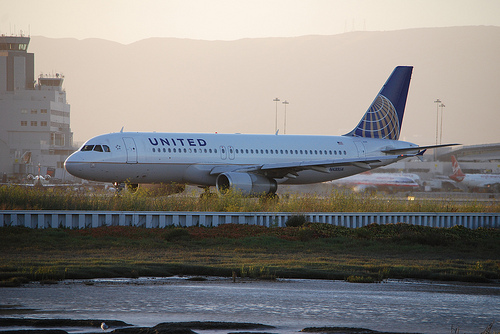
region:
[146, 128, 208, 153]
This airplane says that it is "United"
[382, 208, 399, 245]
There is a white fence that is visible here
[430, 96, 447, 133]
There are large lamps that are visible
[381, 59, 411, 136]
There is a blue tail that is on this airplane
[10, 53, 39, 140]
There is a gray building that is visible here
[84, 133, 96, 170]
There is a small window that is visible here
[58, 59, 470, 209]
airplane on tarmac near airport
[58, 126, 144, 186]
nose of airplane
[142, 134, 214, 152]
name of company that owns the airplane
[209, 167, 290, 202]
jet engine of the left wing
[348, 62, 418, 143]
tail of the United airplae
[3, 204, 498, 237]
fence near the tarmac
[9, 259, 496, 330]
water in pond near the tarmac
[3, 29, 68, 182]
airport and control tower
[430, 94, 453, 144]
light poles at airport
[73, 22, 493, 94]
mountains near the airport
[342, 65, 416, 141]
Image of a globe on blue tail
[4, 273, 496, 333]
Water beside airport runway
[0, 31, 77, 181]
Air traffic control tower on building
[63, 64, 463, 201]
Large commercial airliner parked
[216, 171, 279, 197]
Engine on an airplane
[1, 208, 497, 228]
White retaining wall beside runway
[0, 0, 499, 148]
Hazy daytime sky behind plane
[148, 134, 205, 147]
United logo printed on plane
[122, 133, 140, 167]
Entry door to plane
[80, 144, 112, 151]
Cockpit windows on plane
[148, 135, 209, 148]
A logo on the side of a plane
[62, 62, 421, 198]
A large plane on the ground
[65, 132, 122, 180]
The cockpit of a plane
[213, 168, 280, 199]
A plane's engine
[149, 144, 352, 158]
A row of windows along a plane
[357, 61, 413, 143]
The colored tail wing of the plane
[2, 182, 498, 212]
A line of grass and weeds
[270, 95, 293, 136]
Light posts on the airport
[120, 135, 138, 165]
The door of the plane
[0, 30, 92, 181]
Part of the airport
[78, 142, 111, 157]
Front windows on an airplane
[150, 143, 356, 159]
Side windows on the airplane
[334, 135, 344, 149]
United states flag on the airplane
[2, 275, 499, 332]
Water and a few rocks on the side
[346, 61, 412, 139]
Blue tail on the airplane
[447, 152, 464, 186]
Red tail on the airplane in the back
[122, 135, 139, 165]
Side door on the airplane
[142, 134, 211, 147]
United written on the side of the plane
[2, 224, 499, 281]
A long stretch of grass next to the water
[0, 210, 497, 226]
Long white thin gate wish a patch of grass on it